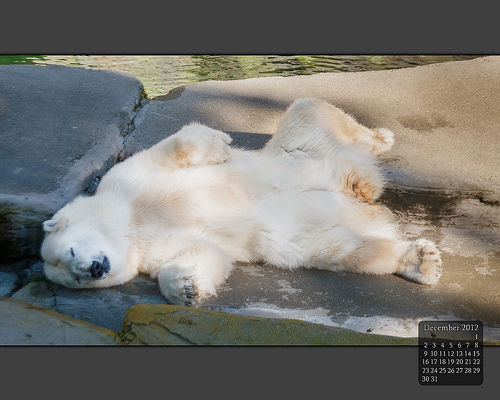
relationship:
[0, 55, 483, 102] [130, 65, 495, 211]
water beyond rock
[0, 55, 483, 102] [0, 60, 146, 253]
water beyond rock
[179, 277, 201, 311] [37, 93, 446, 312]
claws on bear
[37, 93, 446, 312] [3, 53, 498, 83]
bear near water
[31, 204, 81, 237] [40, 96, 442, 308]
ear on bear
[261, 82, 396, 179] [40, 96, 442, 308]
leg on bear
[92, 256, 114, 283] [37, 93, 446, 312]
nose on bear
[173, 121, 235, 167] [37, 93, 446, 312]
paw on bear